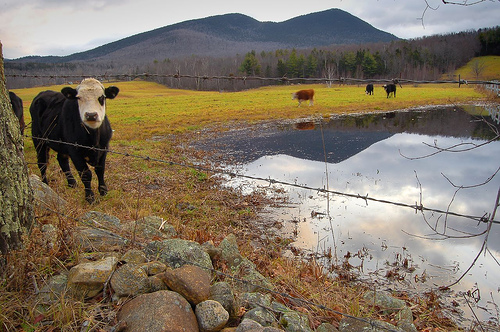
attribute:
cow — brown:
[288, 85, 321, 104]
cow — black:
[361, 81, 374, 93]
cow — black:
[385, 79, 396, 99]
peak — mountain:
[303, 9, 373, 36]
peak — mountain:
[200, 9, 270, 33]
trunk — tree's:
[13, 157, 60, 284]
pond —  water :
[202, 104, 496, 304]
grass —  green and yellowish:
[118, 77, 298, 133]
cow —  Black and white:
[27, 73, 125, 203]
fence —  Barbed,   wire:
[136, 68, 266, 89]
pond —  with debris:
[178, 126, 498, 315]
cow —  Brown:
[293, 90, 318, 102]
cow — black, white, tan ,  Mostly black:
[33, 75, 120, 202]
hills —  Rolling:
[2, 6, 416, 86]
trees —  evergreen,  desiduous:
[246, 46, 393, 78]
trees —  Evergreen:
[242, 50, 387, 90]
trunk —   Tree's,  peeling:
[0, 88, 29, 284]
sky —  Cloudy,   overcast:
[0, 2, 158, 56]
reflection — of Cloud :
[204, 131, 494, 314]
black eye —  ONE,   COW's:
[98, 97, 108, 107]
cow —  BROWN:
[291, 90, 318, 106]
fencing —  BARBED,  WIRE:
[167, 71, 259, 89]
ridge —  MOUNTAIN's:
[154, 10, 386, 51]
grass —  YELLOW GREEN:
[120, 75, 296, 129]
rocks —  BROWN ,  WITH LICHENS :
[111, 291, 209, 329]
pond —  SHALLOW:
[173, 108, 496, 162]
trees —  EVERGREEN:
[247, 42, 370, 78]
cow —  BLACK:
[29, 77, 129, 206]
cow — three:
[379, 79, 397, 99]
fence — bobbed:
[12, 71, 496, 92]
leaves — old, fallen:
[179, 147, 485, 328]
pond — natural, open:
[172, 105, 495, 328]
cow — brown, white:
[291, 89, 313, 103]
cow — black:
[380, 79, 396, 96]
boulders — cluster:
[15, 173, 314, 330]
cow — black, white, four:
[28, 79, 117, 201]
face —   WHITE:
[73, 76, 106, 129]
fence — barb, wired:
[20, 131, 495, 330]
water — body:
[183, 105, 496, 329]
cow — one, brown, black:
[289, 86, 315, 105]